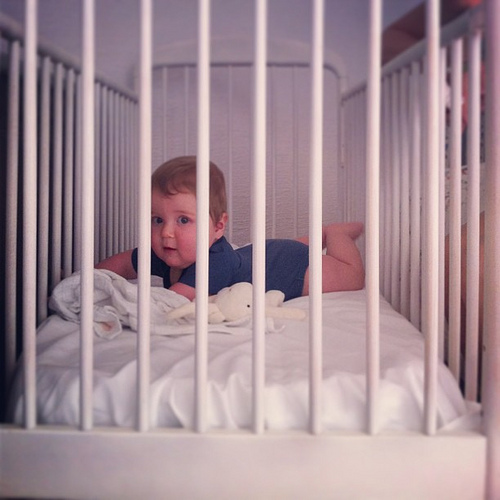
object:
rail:
[22, 0, 39, 429]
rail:
[367, 0, 381, 434]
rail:
[309, 0, 324, 432]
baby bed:
[0, 1, 484, 496]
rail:
[420, 1, 439, 436]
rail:
[249, 0, 267, 434]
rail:
[192, 0, 211, 431]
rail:
[137, 0, 150, 430]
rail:
[3, 39, 20, 393]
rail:
[37, 54, 48, 331]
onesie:
[130, 235, 309, 301]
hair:
[152, 156, 227, 227]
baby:
[93, 154, 364, 302]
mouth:
[163, 245, 177, 252]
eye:
[177, 216, 191, 226]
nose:
[160, 221, 176, 238]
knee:
[346, 261, 366, 291]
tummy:
[245, 277, 286, 298]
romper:
[130, 233, 310, 303]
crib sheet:
[8, 272, 469, 435]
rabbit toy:
[166, 281, 307, 324]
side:
[1, 12, 141, 420]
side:
[2, 2, 482, 498]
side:
[342, 2, 484, 401]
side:
[133, 29, 344, 248]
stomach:
[252, 278, 286, 300]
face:
[151, 186, 198, 268]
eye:
[153, 217, 164, 225]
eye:
[173, 214, 192, 224]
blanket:
[45, 268, 287, 342]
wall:
[2, 2, 426, 323]